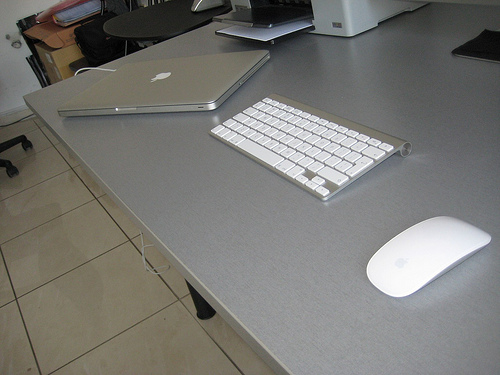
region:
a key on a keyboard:
[318, 185, 328, 195]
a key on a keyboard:
[305, 180, 317, 189]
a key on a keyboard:
[311, 173, 324, 186]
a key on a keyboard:
[298, 172, 308, 182]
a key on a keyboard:
[319, 165, 349, 185]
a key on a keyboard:
[346, 153, 369, 177]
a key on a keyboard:
[335, 159, 352, 172]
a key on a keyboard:
[326, 152, 338, 165]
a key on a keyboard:
[363, 144, 383, 160]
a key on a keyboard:
[381, 142, 395, 151]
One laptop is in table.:
[75, 45, 455, 290]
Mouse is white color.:
[363, 201, 486, 314]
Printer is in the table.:
[227, 1, 375, 56]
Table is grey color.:
[191, 188, 330, 327]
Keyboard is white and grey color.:
[246, 101, 403, 216]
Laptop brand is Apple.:
[111, 49, 266, 114]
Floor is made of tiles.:
[19, 257, 190, 374]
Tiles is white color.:
[11, 246, 220, 351]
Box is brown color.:
[11, 13, 111, 85]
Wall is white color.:
[1, 36, 31, 121]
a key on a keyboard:
[314, 183, 329, 197]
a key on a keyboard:
[286, 165, 303, 179]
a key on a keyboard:
[274, 154, 291, 179]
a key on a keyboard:
[333, 146, 348, 158]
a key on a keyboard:
[318, 152, 331, 164]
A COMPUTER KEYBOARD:
[203, 99, 413, 199]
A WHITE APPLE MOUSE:
[347, 199, 494, 310]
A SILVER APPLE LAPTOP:
[43, 45, 293, 125]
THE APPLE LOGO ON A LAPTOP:
[141, 64, 181, 88]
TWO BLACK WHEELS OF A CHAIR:
[1, 131, 41, 188]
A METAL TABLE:
[25, 61, 487, 351]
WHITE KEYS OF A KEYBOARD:
[208, 91, 414, 202]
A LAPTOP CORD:
[57, 56, 134, 84]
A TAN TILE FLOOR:
[9, 213, 166, 359]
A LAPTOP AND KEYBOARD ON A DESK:
[48, 48, 434, 216]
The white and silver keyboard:
[205, 91, 414, 205]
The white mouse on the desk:
[362, 213, 492, 298]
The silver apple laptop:
[53, 46, 271, 118]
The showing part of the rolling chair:
[0, 135, 34, 180]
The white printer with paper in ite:
[207, 0, 434, 43]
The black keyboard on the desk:
[450, 25, 499, 62]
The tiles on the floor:
[2, 106, 274, 373]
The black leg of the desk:
[178, 262, 215, 320]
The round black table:
[100, 0, 227, 42]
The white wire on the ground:
[135, 228, 171, 278]